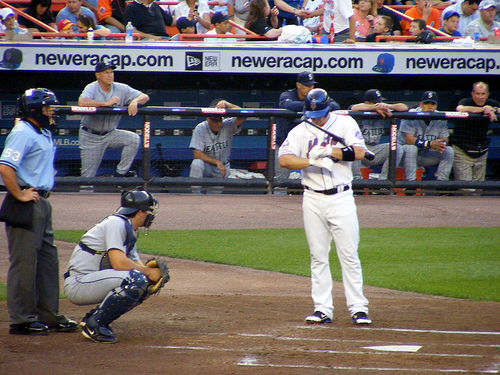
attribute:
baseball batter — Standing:
[271, 81, 379, 323]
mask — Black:
[143, 189, 160, 234]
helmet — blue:
[301, 86, 335, 119]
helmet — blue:
[296, 88, 342, 127]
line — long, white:
[293, 318, 499, 341]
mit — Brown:
[142, 255, 169, 298]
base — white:
[361, 338, 427, 358]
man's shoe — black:
[19, 301, 86, 344]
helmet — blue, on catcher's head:
[114, 195, 160, 227]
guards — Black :
[73, 273, 155, 345]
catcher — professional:
[64, 190, 169, 343]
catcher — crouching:
[57, 187, 165, 349]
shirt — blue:
[35, 146, 58, 193]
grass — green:
[57, 230, 83, 240]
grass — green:
[140, 230, 211, 255]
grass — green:
[225, 227, 298, 267]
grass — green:
[369, 228, 494, 252]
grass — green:
[390, 255, 498, 287]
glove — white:
[308, 145, 333, 159]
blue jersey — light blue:
[0, 116, 57, 194]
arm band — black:
[336, 147, 363, 160]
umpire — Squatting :
[0, 86, 87, 333]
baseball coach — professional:
[454, 80, 499, 167]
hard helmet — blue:
[305, 89, 327, 119]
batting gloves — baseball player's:
[296, 135, 343, 180]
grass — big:
[380, 217, 448, 302]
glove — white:
[135, 250, 171, 309]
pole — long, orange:
[376, 32, 453, 41]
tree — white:
[444, 235, 467, 271]